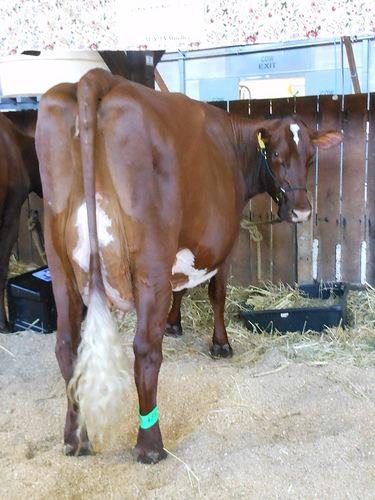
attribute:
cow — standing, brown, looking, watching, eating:
[67, 75, 331, 251]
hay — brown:
[259, 271, 311, 310]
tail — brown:
[65, 138, 118, 322]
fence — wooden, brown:
[325, 177, 357, 225]